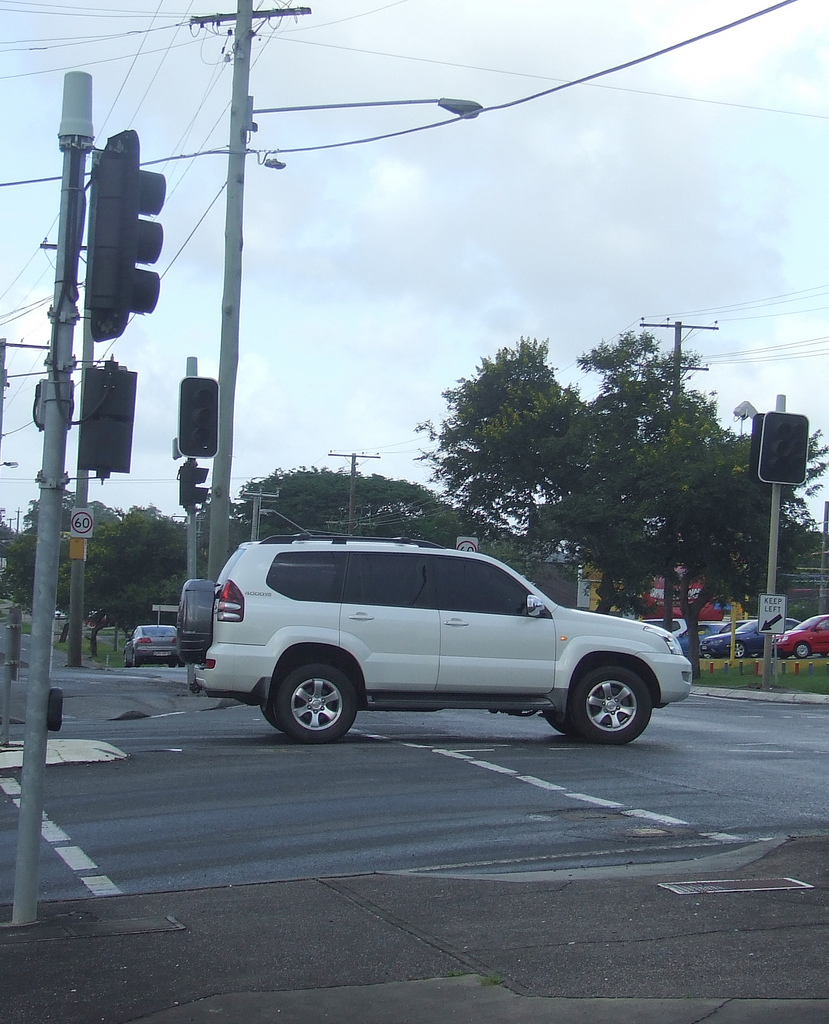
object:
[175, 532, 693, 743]
vehicle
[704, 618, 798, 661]
car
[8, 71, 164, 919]
street light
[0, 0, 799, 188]
wires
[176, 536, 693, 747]
car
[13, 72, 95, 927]
pole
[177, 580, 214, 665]
spare tire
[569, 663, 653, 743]
tire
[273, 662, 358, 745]
tire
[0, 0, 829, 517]
sky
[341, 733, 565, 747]
shadow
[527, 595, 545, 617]
view mirror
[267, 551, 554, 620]
window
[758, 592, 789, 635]
sign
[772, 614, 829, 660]
car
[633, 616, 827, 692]
parking lot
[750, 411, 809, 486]
traffic signal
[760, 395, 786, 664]
pole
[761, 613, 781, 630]
arrow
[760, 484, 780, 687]
pole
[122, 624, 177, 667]
car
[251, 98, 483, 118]
light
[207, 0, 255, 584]
pole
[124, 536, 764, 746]
cars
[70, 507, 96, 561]
traffic sign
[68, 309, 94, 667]
pole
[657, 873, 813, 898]
sewage drain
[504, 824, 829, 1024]
sidewalk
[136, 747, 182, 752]
paper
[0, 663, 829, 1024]
ground